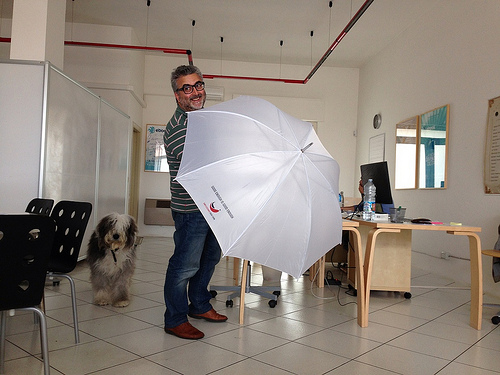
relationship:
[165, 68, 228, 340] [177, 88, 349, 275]
man holding an umbrella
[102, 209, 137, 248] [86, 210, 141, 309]
head of a dog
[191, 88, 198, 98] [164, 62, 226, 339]
nose of a man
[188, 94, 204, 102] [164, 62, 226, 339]
mouth of a man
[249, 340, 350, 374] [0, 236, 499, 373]
tile of a floor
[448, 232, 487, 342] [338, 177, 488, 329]
leg under table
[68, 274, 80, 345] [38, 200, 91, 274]
leg on chair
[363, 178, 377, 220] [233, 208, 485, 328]
bottle on desk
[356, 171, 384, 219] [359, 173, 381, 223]
bottle holding water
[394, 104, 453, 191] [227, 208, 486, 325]
sign behind desk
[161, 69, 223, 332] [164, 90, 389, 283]
man holding umbrella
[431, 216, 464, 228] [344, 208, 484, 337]
posted notes on table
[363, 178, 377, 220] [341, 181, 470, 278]
bottle on table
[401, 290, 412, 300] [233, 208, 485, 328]
wheel under desk